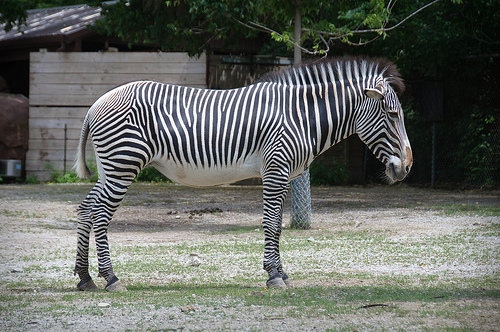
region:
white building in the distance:
[16, 25, 310, 182]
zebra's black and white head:
[333, 55, 428, 177]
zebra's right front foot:
[247, 262, 290, 298]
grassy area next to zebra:
[153, 227, 437, 322]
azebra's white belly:
[151, 155, 254, 200]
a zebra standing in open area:
[53, 40, 420, 309]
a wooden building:
[23, 50, 210, 190]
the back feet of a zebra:
[63, 214, 133, 298]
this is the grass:
[327, 284, 359, 307]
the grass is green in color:
[305, 287, 334, 304]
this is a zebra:
[55, 54, 429, 299]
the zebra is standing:
[71, 47, 415, 298]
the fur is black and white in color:
[178, 102, 250, 142]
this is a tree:
[258, 7, 365, 55]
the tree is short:
[288, 7, 325, 52]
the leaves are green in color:
[356, 11, 380, 25]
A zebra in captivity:
[55, 50, 420, 300]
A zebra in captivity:
[56, 50, 416, 296]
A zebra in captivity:
[62, 52, 417, 298]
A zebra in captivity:
[66, 50, 416, 291]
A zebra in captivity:
[61, 50, 411, 295]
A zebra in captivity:
[70, 51, 415, 296]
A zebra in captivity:
[70, 55, 415, 295]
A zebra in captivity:
[70, 55, 415, 305]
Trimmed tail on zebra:
[64, 116, 96, 183]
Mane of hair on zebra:
[257, 57, 404, 84]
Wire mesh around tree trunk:
[288, 172, 312, 227]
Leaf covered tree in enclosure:
[161, 0, 431, 227]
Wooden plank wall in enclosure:
[26, 52, 206, 183]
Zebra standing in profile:
[63, 50, 414, 292]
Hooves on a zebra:
[76, 274, 293, 294]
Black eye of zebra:
[383, 109, 405, 119]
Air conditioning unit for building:
[3, 153, 23, 180]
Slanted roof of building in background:
[3, 2, 115, 41]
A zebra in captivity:
[62, 46, 423, 301]